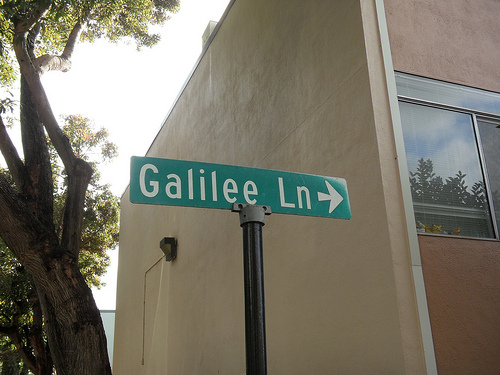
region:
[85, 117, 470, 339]
a street sign on a pole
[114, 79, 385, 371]
street sign on a metal pole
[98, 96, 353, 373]
sign on a metal pole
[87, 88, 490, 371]
green and white sign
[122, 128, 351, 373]
green and white street sign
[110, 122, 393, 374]
green and white sign on pole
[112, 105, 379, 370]
green and white sign on metal pole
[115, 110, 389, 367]
a green and white street sign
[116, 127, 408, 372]
a green and white street sign on a pole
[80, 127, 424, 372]
a green and white street sign on a metal pole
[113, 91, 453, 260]
Green sign on the pole.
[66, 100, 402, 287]
Green sign with white writing.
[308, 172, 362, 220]
Arrow on the sign.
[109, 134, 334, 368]
Pole with a green sign.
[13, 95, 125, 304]
Green leaves on the tree.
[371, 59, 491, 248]
Window on the building.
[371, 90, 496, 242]
Tree reflected in the window.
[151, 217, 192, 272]
Light on the building.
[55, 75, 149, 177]
Sky behind the building.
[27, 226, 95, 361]
Trunk of the tree.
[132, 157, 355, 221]
green street name sign with white writing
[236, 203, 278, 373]
black metal street name sign holder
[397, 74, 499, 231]
apartment window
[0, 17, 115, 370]
tall tree with brown trunk and green leaves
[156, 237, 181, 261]
outside light on apartment wall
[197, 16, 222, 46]
air condition unit on top of apartment building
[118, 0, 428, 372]
beige side outdoor wall of apartment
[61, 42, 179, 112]
sky above apartment building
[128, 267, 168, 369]
outdoor electrical wire holder for light on side of apartment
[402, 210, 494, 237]
white blinds in apartment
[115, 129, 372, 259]
the sign is green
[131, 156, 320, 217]
white letters on sign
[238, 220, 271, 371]
the pole is made of metal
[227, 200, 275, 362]
the pole is black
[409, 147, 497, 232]
reflection of tree on window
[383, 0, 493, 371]
the building is orange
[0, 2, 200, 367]
tree next to building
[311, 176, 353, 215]
white arrow on sign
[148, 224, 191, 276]
black lamp on building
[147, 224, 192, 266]
lamp on side of building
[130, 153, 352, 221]
Green street sign on black metal pole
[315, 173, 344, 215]
White arrow printed on green street sign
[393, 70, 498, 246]
Window on building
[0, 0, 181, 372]
Tree next to building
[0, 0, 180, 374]
Tree by green street sign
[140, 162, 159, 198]
White letter G on green street sign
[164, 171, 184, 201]
White letter A on green street sign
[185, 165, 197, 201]
White letter L on green street sign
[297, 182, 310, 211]
White letter N on green street sign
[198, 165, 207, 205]
White letter I on green street sign